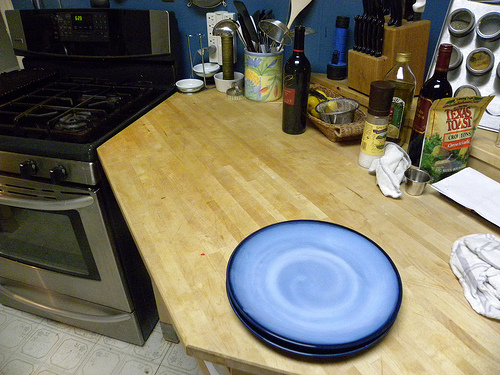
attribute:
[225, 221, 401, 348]
plate — blue, light, dark blue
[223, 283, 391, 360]
plate — blue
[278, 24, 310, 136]
wine — black, dark, bottle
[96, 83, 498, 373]
counter — wooden, wood, brown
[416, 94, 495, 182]
crouton bag — yellow, green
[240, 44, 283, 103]
utensil holder — floral, brightly colored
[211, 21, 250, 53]
soup spoon — silver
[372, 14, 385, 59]
knife — black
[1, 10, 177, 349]
stove — black, silver, steel, stainless steel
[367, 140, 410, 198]
towel — white, gray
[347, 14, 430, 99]
knife block — wood, wooden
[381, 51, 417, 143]
olive oil — bottle, plastic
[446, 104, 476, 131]
lettering — red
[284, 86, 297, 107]
label — red, rectangle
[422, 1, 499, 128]
spice rack — gray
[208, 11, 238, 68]
outlet strip — light colored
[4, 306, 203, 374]
floor — tiled, white